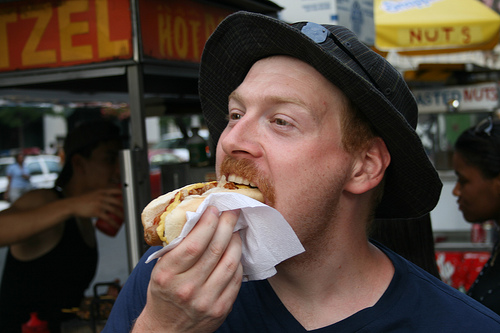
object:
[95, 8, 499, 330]
person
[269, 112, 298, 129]
eye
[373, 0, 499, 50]
nuts umbrella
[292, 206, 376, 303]
neck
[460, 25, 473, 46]
letter s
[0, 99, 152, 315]
lady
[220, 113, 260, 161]
nose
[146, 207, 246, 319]
fingers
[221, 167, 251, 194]
teeth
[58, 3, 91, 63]
e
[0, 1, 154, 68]
sign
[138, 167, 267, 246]
hotdog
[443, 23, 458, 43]
t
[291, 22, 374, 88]
sunglasses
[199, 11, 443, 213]
hat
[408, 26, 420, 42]
n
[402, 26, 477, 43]
sign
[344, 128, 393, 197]
ear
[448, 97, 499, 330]
person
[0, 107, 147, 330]
person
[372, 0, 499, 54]
cover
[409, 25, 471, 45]
nuts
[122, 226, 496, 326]
shirt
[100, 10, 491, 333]
man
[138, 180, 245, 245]
hot dog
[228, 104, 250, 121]
eyes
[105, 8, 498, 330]
guy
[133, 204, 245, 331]
hand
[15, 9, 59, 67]
z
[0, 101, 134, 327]
woman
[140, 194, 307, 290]
napkin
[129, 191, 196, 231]
ketchup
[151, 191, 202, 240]
mustard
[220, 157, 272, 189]
mustache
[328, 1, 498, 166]
stand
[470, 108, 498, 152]
sunglasses